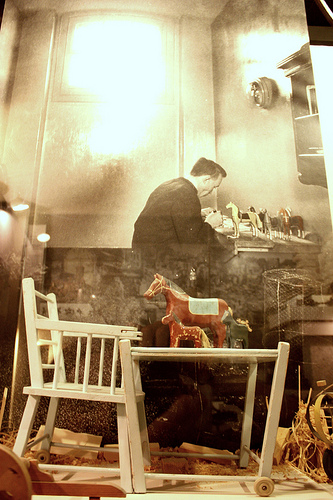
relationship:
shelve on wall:
[2, 49, 174, 234] [20, 145, 156, 263]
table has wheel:
[202, 209, 314, 340] [262, 359, 306, 378]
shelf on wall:
[103, 122, 188, 218] [20, 145, 156, 263]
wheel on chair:
[262, 359, 306, 378] [24, 285, 149, 456]